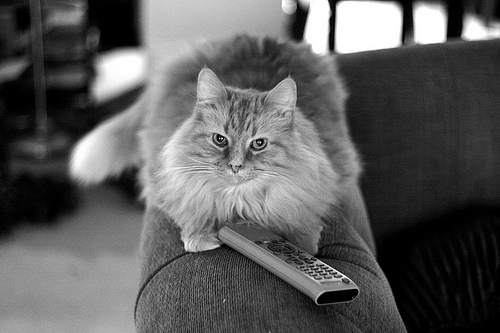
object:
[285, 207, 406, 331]
back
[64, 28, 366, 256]
cat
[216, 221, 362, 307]
control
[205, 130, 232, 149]
eye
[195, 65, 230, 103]
ear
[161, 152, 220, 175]
whiskers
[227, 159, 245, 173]
nose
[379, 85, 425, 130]
part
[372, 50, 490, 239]
sofa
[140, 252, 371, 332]
arm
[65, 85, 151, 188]
tail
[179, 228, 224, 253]
paw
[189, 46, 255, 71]
fur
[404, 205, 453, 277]
cush